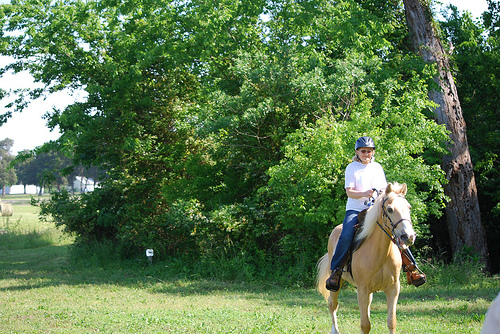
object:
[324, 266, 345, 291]
shoe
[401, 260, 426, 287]
shoe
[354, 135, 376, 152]
helmet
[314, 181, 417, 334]
horse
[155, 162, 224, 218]
leaves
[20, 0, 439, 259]
tree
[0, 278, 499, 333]
ground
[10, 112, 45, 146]
sky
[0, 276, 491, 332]
grass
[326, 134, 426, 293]
man